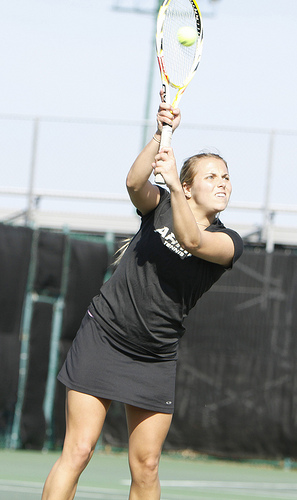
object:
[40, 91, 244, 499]
lady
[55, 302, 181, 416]
dress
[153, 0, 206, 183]
bat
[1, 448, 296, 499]
ground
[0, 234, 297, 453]
screen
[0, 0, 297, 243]
sky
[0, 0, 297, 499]
day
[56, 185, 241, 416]
clothes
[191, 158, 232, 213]
face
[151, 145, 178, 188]
hands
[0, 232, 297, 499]
court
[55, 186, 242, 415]
black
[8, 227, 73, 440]
blue-green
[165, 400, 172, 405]
writing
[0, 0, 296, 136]
above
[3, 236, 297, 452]
structure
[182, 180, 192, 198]
ear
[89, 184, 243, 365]
top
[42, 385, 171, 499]
pair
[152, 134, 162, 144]
piece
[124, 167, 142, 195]
elbow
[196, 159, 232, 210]
grimace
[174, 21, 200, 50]
collision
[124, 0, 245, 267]
volley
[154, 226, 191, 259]
logo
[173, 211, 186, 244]
muscle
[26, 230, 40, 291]
poles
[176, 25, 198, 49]
tennis ball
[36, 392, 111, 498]
legs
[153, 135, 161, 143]
jewelry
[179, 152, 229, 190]
hair